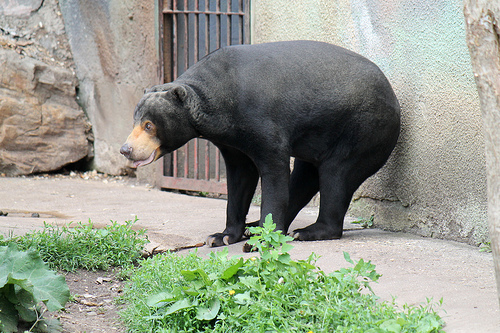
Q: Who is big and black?
A: A bear.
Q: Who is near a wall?
A: A bear.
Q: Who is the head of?
A: A bear.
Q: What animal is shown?
A: A bear.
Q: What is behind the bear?
A: A wall.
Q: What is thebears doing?
A: Standing.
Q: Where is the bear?
A: In a zoo.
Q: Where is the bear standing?
A: On the concrete.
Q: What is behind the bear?
A: A doorway.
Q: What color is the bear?
A: Black and brown.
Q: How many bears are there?
A: One.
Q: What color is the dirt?
A: Brown.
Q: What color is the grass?
A: Green.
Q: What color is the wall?
A: Gray.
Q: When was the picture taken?
A: Daytime.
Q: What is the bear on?
A: Cement.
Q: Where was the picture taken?
A: In a zoo.